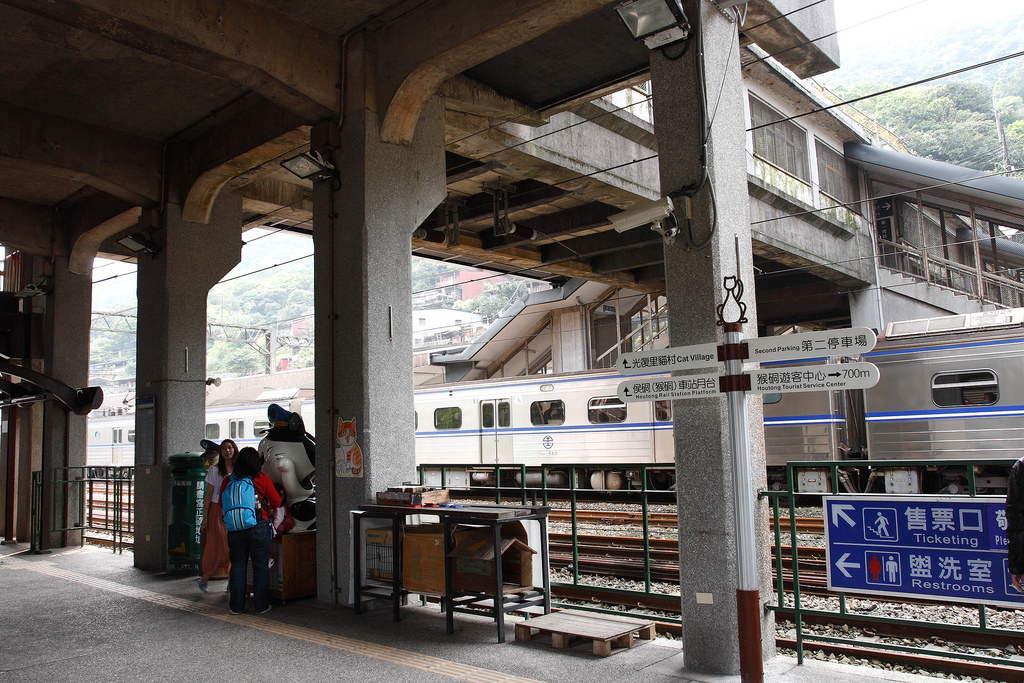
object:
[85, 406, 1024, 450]
stripe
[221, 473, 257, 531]
backpack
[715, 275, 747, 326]
cat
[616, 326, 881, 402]
asian language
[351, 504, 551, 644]
table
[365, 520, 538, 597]
bottom shelf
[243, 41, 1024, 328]
covered walkway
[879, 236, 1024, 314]
stairway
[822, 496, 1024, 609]
sign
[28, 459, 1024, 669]
fence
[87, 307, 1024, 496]
car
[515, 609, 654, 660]
wooden palette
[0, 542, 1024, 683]
platform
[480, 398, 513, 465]
door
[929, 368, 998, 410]
window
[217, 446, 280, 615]
passenger